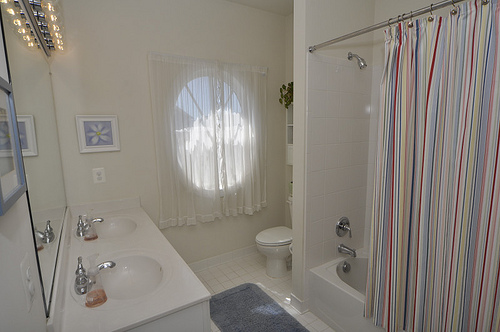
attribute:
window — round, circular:
[176, 80, 257, 195]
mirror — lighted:
[0, 5, 68, 322]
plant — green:
[277, 81, 294, 109]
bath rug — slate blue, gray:
[209, 284, 307, 331]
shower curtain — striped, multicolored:
[363, 0, 500, 331]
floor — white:
[188, 247, 338, 332]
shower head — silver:
[348, 49, 369, 71]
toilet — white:
[255, 195, 294, 276]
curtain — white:
[152, 56, 267, 219]